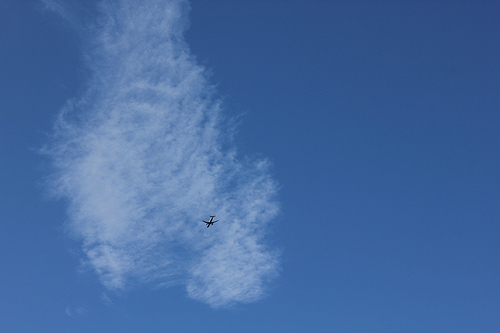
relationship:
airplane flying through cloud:
[199, 214, 223, 230] [42, 33, 299, 300]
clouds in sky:
[44, 1, 286, 310] [0, 0, 496, 332]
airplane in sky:
[199, 214, 223, 230] [0, 0, 496, 332]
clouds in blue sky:
[22, 0, 287, 317] [1, 1, 498, 331]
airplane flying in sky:
[199, 214, 223, 230] [72, 50, 363, 301]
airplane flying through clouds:
[199, 214, 223, 230] [44, 1, 286, 310]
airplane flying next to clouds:
[199, 214, 223, 230] [44, 1, 286, 310]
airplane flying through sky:
[203, 214, 220, 230] [0, 0, 496, 332]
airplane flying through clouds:
[199, 214, 223, 230] [22, 0, 287, 317]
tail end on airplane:
[209, 213, 216, 220] [199, 214, 223, 230]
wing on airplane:
[201, 217, 207, 226] [200, 213, 219, 229]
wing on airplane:
[213, 217, 219, 225] [200, 213, 219, 229]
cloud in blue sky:
[56, 297, 85, 318] [1, 1, 498, 331]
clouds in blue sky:
[44, 1, 286, 310] [1, 1, 498, 331]